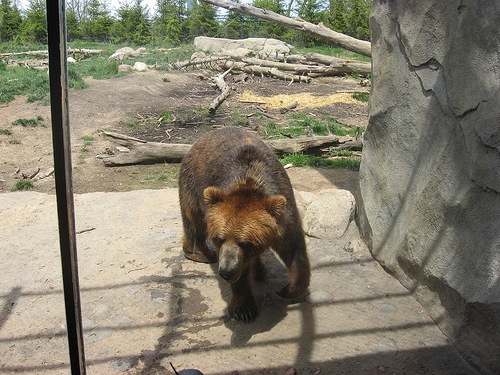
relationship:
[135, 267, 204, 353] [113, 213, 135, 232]
water stain on ground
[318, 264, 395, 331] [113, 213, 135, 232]
shadow lines on ground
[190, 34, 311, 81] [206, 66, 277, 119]
pile of logs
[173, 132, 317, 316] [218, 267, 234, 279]
bear has nose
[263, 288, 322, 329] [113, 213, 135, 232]
shadow on ground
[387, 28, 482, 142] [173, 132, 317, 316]
rock wall next to bear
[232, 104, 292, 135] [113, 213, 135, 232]
branches on ground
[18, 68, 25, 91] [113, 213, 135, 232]
grass on ground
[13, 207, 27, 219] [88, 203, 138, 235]
part of floor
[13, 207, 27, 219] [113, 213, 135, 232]
part of ground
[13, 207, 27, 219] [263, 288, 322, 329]
part of shadow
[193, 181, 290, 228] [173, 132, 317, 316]
ears of bear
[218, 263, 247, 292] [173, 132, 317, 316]
nose of bear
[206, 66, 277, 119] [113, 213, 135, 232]
logs on ground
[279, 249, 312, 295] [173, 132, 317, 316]
front leg of bear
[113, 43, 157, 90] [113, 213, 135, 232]
rocks on ground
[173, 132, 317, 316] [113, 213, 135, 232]
bear on ground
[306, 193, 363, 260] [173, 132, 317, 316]
rock near bear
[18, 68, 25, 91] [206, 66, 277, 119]
grass under logs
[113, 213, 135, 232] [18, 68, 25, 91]
ground near grass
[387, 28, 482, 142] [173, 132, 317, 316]
rock wall by bear